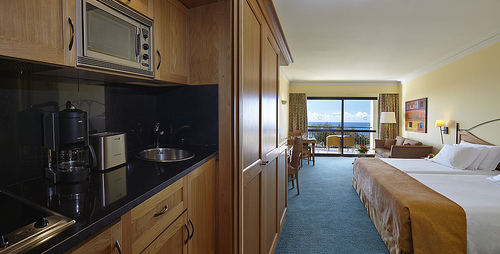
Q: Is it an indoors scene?
A: Yes, it is indoors.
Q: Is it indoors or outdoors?
A: It is indoors.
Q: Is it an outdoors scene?
A: No, it is indoors.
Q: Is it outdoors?
A: No, it is indoors.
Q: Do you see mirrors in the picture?
A: No, there are no mirrors.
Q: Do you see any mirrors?
A: No, there are no mirrors.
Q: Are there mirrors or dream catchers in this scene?
A: No, there are no mirrors or dream catchers.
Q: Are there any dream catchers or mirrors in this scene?
A: No, there are no mirrors or dream catchers.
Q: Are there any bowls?
A: No, there are no bowls.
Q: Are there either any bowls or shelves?
A: No, there are no bowls or shelves.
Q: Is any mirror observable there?
A: No, there are no mirrors.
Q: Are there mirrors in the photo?
A: No, there are no mirrors.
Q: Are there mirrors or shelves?
A: No, there are no mirrors or shelves.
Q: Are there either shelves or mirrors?
A: No, there are no mirrors or shelves.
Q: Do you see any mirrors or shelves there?
A: No, there are no mirrors or shelves.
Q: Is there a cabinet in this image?
A: Yes, there is a cabinet.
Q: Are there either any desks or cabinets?
A: Yes, there is a cabinet.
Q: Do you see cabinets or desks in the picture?
A: Yes, there is a cabinet.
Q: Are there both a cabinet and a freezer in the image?
A: No, there is a cabinet but no refrigerators.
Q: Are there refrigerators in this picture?
A: No, there are no refrigerators.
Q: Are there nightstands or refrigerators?
A: No, there are no refrigerators or nightstands.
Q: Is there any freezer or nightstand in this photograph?
A: No, there are no refrigerators or nightstands.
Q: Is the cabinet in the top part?
A: Yes, the cabinet is in the top of the image.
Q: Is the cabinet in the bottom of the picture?
A: No, the cabinet is in the top of the image.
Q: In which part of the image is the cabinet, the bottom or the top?
A: The cabinet is in the top of the image.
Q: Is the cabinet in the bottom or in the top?
A: The cabinet is in the top of the image.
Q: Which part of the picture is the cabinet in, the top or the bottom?
A: The cabinet is in the top of the image.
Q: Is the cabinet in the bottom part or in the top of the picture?
A: The cabinet is in the top of the image.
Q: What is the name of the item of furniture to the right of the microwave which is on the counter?
A: The piece of furniture is a cabinet.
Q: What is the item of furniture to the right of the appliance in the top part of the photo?
A: The piece of furniture is a cabinet.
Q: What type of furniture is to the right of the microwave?
A: The piece of furniture is a cabinet.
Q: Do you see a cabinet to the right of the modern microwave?
A: Yes, there is a cabinet to the right of the microwave.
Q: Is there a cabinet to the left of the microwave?
A: No, the cabinet is to the right of the microwave.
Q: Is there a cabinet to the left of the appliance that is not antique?
A: No, the cabinet is to the right of the microwave.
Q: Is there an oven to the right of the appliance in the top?
A: No, there is a cabinet to the right of the microwave.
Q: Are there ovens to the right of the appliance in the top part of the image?
A: No, there is a cabinet to the right of the microwave.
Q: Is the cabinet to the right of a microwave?
A: Yes, the cabinet is to the right of a microwave.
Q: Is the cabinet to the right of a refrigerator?
A: No, the cabinet is to the right of a microwave.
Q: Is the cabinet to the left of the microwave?
A: No, the cabinet is to the right of the microwave.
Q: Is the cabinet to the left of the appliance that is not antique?
A: No, the cabinet is to the right of the microwave.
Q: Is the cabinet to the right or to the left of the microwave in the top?
A: The cabinet is to the right of the microwave.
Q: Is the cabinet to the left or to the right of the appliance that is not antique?
A: The cabinet is to the right of the microwave.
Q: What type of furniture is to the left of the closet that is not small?
A: The piece of furniture is a cabinet.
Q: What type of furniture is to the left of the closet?
A: The piece of furniture is a cabinet.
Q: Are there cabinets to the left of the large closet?
A: Yes, there is a cabinet to the left of the closet.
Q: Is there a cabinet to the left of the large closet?
A: Yes, there is a cabinet to the left of the closet.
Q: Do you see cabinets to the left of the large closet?
A: Yes, there is a cabinet to the left of the closet.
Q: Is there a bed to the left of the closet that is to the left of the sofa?
A: No, there is a cabinet to the left of the closet.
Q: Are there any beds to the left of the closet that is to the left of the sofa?
A: No, there is a cabinet to the left of the closet.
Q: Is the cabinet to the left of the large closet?
A: Yes, the cabinet is to the left of the closet.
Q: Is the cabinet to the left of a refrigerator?
A: No, the cabinet is to the left of the closet.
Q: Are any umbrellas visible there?
A: No, there are no umbrellas.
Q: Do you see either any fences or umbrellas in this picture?
A: No, there are no umbrellas or fences.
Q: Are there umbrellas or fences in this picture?
A: No, there are no umbrellas or fences.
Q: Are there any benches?
A: Yes, there is a bench.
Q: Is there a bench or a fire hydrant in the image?
A: Yes, there is a bench.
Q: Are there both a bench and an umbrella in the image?
A: No, there is a bench but no umbrellas.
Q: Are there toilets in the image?
A: No, there are no toilets.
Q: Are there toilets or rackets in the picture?
A: No, there are no toilets or rackets.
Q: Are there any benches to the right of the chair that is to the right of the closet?
A: Yes, there is a bench to the right of the chair.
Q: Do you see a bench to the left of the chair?
A: No, the bench is to the right of the chair.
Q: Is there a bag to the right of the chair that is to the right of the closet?
A: No, there is a bench to the right of the chair.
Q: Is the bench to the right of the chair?
A: Yes, the bench is to the right of the chair.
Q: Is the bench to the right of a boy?
A: No, the bench is to the right of the chair.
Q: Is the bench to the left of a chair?
A: No, the bench is to the right of a chair.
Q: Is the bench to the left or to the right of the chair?
A: The bench is to the right of the chair.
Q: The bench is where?
A: The bench is on the balcony.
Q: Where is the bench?
A: The bench is on the balcony.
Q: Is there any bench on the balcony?
A: Yes, there is a bench on the balcony.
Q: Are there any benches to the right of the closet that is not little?
A: Yes, there is a bench to the right of the closet.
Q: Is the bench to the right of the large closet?
A: Yes, the bench is to the right of the closet.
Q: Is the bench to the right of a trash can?
A: No, the bench is to the right of the closet.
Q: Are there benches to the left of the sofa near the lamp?
A: Yes, there is a bench to the left of the sofa.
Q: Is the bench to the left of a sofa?
A: Yes, the bench is to the left of a sofa.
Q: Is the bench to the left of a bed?
A: No, the bench is to the left of a sofa.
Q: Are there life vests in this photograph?
A: No, there are no life vests.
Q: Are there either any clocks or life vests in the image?
A: No, there are no life vests or clocks.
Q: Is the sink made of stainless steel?
A: Yes, the sink is made of stainless steel.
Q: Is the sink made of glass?
A: No, the sink is made of stainless steel.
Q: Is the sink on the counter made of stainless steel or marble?
A: The sink is made of stainless steel.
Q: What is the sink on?
A: The sink is on the counter.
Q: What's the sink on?
A: The sink is on the counter.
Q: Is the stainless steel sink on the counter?
A: Yes, the sink is on the counter.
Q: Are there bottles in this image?
A: No, there are no bottles.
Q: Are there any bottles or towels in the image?
A: No, there are no bottles or towels.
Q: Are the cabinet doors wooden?
A: Yes, the cabinet doors are wooden.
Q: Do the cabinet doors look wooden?
A: Yes, the cabinet doors are wooden.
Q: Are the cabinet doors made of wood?
A: Yes, the cabinet doors are made of wood.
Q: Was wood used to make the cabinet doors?
A: Yes, the cabinet doors are made of wood.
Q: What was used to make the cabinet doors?
A: The cabinet doors are made of wood.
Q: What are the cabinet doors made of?
A: The cabinet doors are made of wood.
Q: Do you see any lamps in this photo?
A: Yes, there is a lamp.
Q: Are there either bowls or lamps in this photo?
A: Yes, there is a lamp.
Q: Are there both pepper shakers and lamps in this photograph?
A: No, there is a lamp but no pepper shakers.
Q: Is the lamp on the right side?
A: Yes, the lamp is on the right of the image.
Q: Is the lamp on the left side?
A: No, the lamp is on the right of the image.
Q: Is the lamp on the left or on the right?
A: The lamp is on the right of the image.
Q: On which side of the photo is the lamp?
A: The lamp is on the right of the image.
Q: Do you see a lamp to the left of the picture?
A: Yes, there is a lamp to the left of the picture.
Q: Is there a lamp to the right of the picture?
A: No, the lamp is to the left of the picture.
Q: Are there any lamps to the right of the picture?
A: No, the lamp is to the left of the picture.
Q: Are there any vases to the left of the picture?
A: No, there is a lamp to the left of the picture.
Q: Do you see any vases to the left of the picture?
A: No, there is a lamp to the left of the picture.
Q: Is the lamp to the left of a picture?
A: Yes, the lamp is to the left of a picture.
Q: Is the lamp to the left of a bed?
A: No, the lamp is to the left of a picture.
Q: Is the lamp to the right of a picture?
A: No, the lamp is to the left of a picture.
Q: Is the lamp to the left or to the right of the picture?
A: The lamp is to the left of the picture.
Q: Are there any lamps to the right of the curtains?
A: Yes, there is a lamp to the right of the curtains.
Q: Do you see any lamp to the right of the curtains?
A: Yes, there is a lamp to the right of the curtains.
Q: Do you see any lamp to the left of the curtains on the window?
A: No, the lamp is to the right of the curtains.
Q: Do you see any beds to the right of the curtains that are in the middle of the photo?
A: No, there is a lamp to the right of the curtains.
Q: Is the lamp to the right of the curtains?
A: Yes, the lamp is to the right of the curtains.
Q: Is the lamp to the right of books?
A: No, the lamp is to the right of the curtains.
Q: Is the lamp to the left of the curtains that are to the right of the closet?
A: No, the lamp is to the right of the curtains.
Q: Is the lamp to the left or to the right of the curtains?
A: The lamp is to the right of the curtains.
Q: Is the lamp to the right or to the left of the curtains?
A: The lamp is to the right of the curtains.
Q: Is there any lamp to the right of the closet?
A: Yes, there is a lamp to the right of the closet.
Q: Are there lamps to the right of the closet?
A: Yes, there is a lamp to the right of the closet.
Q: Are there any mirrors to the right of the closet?
A: No, there is a lamp to the right of the closet.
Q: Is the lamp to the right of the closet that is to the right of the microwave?
A: Yes, the lamp is to the right of the closet.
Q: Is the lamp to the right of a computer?
A: No, the lamp is to the right of the closet.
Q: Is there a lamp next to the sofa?
A: Yes, there is a lamp next to the sofa.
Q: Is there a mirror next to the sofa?
A: No, there is a lamp next to the sofa.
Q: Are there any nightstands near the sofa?
A: No, there is a lamp near the sofa.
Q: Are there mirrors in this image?
A: No, there are no mirrors.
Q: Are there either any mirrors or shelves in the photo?
A: No, there are no mirrors or shelves.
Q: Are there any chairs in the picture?
A: Yes, there is a chair.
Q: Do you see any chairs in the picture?
A: Yes, there is a chair.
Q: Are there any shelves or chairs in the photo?
A: Yes, there is a chair.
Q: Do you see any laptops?
A: No, there are no laptops.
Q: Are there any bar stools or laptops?
A: No, there are no laptops or bar stools.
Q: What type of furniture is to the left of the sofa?
A: The piece of furniture is a chair.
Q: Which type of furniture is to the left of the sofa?
A: The piece of furniture is a chair.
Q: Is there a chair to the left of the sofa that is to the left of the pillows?
A: Yes, there is a chair to the left of the sofa.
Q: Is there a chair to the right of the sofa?
A: No, the chair is to the left of the sofa.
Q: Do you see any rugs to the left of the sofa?
A: No, there is a chair to the left of the sofa.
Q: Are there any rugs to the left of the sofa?
A: No, there is a chair to the left of the sofa.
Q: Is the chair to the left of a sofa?
A: Yes, the chair is to the left of a sofa.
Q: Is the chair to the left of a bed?
A: No, the chair is to the left of a sofa.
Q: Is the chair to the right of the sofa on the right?
A: No, the chair is to the left of the sofa.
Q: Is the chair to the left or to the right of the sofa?
A: The chair is to the left of the sofa.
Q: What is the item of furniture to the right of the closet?
A: The piece of furniture is a chair.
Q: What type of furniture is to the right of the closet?
A: The piece of furniture is a chair.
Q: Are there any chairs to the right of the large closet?
A: Yes, there is a chair to the right of the closet.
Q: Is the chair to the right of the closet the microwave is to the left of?
A: Yes, the chair is to the right of the closet.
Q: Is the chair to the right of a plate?
A: No, the chair is to the right of the closet.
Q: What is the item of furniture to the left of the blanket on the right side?
A: The piece of furniture is a chair.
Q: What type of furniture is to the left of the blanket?
A: The piece of furniture is a chair.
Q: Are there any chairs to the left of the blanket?
A: Yes, there is a chair to the left of the blanket.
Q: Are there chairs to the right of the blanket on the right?
A: No, the chair is to the left of the blanket.